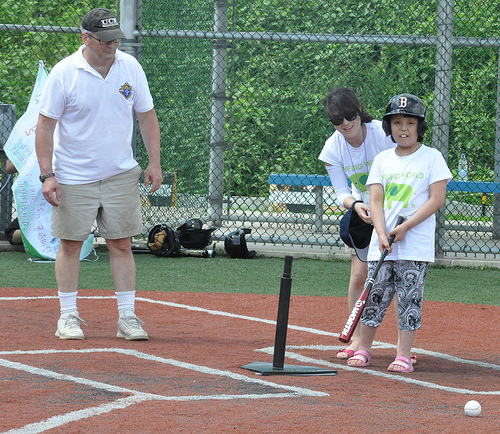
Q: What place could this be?
A: It is a field.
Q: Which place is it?
A: It is a field.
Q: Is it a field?
A: Yes, it is a field.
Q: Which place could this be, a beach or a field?
A: It is a field.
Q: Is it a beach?
A: No, it is a field.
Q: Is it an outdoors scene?
A: Yes, it is outdoors.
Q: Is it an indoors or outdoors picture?
A: It is outdoors.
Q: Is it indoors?
A: No, it is outdoors.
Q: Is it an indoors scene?
A: No, it is outdoors.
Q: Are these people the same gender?
A: No, they are both male and female.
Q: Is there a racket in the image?
A: No, there are no rackets.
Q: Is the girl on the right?
A: Yes, the girl is on the right of the image.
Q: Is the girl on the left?
A: No, the girl is on the right of the image.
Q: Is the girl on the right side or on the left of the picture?
A: The girl is on the right of the image.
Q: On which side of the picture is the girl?
A: The girl is on the right of the image.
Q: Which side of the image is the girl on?
A: The girl is on the right of the image.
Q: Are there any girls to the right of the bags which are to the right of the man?
A: Yes, there is a girl to the right of the bags.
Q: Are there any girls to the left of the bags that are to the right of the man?
A: No, the girl is to the right of the bags.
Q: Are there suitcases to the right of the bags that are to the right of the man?
A: No, there is a girl to the right of the bags.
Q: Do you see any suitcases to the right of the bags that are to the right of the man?
A: No, there is a girl to the right of the bags.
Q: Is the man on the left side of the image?
A: Yes, the man is on the left of the image.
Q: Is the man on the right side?
A: No, the man is on the left of the image.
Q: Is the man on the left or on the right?
A: The man is on the left of the image.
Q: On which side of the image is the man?
A: The man is on the left of the image.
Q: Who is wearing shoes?
A: The man is wearing shoes.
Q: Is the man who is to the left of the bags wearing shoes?
A: Yes, the man is wearing shoes.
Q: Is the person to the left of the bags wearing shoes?
A: Yes, the man is wearing shoes.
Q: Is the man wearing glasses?
A: No, the man is wearing shoes.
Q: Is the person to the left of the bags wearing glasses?
A: No, the man is wearing shoes.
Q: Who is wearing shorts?
A: The man is wearing shorts.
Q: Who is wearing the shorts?
A: The man is wearing shorts.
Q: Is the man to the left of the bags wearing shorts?
A: Yes, the man is wearing shorts.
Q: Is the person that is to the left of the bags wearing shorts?
A: Yes, the man is wearing shorts.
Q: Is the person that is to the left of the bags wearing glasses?
A: No, the man is wearing shorts.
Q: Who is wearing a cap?
A: The man is wearing a cap.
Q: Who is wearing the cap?
A: The man is wearing a cap.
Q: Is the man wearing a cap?
A: Yes, the man is wearing a cap.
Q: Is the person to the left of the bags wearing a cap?
A: Yes, the man is wearing a cap.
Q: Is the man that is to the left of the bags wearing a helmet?
A: No, the man is wearing a cap.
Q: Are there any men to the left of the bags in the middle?
A: Yes, there is a man to the left of the bags.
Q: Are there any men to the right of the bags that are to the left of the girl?
A: No, the man is to the left of the bags.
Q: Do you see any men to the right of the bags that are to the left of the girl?
A: No, the man is to the left of the bags.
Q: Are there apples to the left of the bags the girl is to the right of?
A: No, there is a man to the left of the bags.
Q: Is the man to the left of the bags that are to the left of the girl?
A: Yes, the man is to the left of the bags.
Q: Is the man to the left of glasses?
A: No, the man is to the left of the bags.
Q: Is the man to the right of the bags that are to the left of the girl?
A: No, the man is to the left of the bags.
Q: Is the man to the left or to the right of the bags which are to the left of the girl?
A: The man is to the left of the bags.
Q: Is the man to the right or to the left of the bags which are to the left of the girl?
A: The man is to the left of the bags.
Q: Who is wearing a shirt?
A: The man is wearing a shirt.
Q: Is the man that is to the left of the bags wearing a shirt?
A: Yes, the man is wearing a shirt.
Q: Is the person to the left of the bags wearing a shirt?
A: Yes, the man is wearing a shirt.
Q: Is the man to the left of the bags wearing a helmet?
A: No, the man is wearing a shirt.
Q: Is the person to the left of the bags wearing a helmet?
A: No, the man is wearing a shirt.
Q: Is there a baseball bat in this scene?
A: Yes, there is a baseball bat.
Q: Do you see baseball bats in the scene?
A: Yes, there is a baseball bat.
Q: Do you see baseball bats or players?
A: Yes, there is a baseball bat.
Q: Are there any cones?
A: No, there are no cones.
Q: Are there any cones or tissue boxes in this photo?
A: No, there are no cones or tissue boxes.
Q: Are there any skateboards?
A: No, there are no skateboards.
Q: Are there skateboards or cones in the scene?
A: No, there are no skateboards or cones.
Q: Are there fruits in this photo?
A: No, there are no fruits.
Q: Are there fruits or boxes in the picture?
A: No, there are no fruits or boxes.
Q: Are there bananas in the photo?
A: No, there are no bananas.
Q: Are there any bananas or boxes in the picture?
A: No, there are no bananas or boxes.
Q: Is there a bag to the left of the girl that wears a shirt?
A: Yes, there are bags to the left of the girl.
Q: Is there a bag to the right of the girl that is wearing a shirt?
A: No, the bags are to the left of the girl.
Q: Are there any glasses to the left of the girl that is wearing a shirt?
A: No, there are bags to the left of the girl.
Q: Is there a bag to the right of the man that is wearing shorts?
A: Yes, there are bags to the right of the man.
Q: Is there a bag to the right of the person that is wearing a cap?
A: Yes, there are bags to the right of the man.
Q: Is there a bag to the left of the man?
A: No, the bags are to the right of the man.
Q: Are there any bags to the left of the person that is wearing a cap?
A: No, the bags are to the right of the man.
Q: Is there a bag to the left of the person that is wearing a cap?
A: No, the bags are to the right of the man.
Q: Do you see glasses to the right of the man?
A: No, there are bags to the right of the man.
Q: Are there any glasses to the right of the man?
A: No, there are bags to the right of the man.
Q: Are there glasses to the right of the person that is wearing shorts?
A: No, there are bags to the right of the man.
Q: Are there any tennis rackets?
A: No, there are no tennis rackets.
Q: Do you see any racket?
A: No, there are no rackets.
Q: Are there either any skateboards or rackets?
A: No, there are no rackets or skateboards.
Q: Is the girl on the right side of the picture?
A: Yes, the girl is on the right of the image.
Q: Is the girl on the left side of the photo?
A: No, the girl is on the right of the image.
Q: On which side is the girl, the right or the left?
A: The girl is on the right of the image.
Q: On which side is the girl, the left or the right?
A: The girl is on the right of the image.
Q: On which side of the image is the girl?
A: The girl is on the right of the image.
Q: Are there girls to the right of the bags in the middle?
A: Yes, there is a girl to the right of the bags.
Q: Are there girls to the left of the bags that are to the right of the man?
A: No, the girl is to the right of the bags.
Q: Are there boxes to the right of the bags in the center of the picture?
A: No, there is a girl to the right of the bags.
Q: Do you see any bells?
A: No, there are no bells.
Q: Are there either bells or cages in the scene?
A: No, there are no bells or cages.